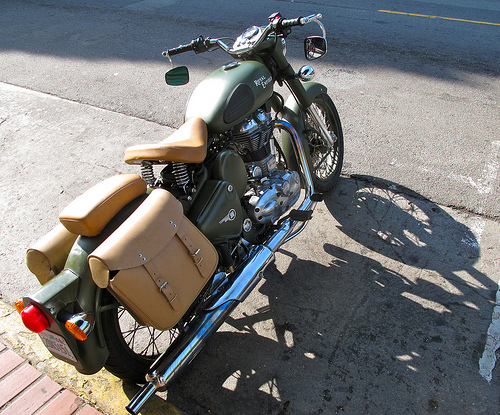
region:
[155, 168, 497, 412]
shadow is being cast by motorcycle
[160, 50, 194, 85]
mirror is attached to handlebar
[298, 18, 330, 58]
mirror is attached to handlebar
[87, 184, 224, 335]
saddlebag is attached to motorcycle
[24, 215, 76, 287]
saddlebag is attached to motorcycle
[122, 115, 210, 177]
seat is attached to motorcycle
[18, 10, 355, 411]
motorcycle is in parking spot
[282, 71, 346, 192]
front wheel is attached to motorcycle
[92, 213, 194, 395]
rear wheel is attached to motorcycle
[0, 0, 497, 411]
road does not have lots of traffic on it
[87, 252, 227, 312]
Brown bag tied to motorcycle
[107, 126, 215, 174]
The seat is tan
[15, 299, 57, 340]
Red taillight on the motorcycle.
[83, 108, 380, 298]
Motorcycle is parked.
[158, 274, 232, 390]
Silver muffler on motorcycle.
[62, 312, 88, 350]
Back light is orange.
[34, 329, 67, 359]
License plate on back of motorcycle.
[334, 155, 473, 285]
Reflection of wheel on sidewalk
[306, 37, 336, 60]
Front mirrors on the motorcycle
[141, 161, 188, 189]
Springs on the seat.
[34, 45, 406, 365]
motorcycle parked on the street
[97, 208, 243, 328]
saddle backs on motorcycle parked on the street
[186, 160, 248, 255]
saddle bag on motorcycle parked on the street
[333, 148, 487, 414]
shadow of motorcycle parked on the street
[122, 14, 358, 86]
handle bars on the motorcycle parked on the street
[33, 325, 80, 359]
license plate on the motorcycle parked on the street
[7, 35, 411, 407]
dark green motorcycle parked on the street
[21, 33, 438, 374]
new motorcycle parked on the street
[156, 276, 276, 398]
exhaust pipe on motorcycle parked on the street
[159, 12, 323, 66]
Handlebars of a motorbike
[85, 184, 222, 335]
A light brown bag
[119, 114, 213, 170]
Brown leather motorbike seat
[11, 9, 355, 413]
A motorcycle on the ground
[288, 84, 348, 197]
The tire is round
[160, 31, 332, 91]
A pair of side mirrors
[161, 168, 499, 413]
Motorbike's shadow on the ground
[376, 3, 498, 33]
Yellow line on the street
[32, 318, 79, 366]
A white license plate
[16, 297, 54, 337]
A red rear light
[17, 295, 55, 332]
A red motorcycle light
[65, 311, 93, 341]
A orange motorcycle light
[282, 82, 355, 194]
A motorcycle black tire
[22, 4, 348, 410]
A big black motorcycle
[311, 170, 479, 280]
The black tire's shadow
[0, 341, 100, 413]
A red brick pathway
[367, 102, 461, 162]
A black tar road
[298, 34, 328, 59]
A mirror on the motorcycle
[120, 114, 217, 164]
The seat of the motorcycle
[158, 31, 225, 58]
The left motorcycle handle